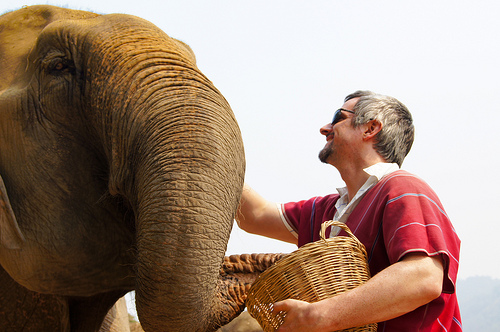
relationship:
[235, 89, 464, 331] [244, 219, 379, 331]
man holding basket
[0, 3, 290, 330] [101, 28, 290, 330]
elephant has trunk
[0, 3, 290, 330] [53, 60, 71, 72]
elephant has right eye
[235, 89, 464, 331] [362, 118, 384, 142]
man has left ear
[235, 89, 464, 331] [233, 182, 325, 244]
man has right arm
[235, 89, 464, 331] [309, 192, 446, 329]
man has left arm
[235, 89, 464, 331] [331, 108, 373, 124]
man wearing sunglasses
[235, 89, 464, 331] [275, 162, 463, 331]
man wearing shirt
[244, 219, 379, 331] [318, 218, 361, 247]
basket has handle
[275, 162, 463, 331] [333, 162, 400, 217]
shirt has collar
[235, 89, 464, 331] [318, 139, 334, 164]
man has goatee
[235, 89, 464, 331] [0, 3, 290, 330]
man with elephant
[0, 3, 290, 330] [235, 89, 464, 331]
elephant standing by man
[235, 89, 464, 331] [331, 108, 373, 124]
man with sunglasses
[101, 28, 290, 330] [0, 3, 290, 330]
trunk on front of elephant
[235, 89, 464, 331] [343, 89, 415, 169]
man has hair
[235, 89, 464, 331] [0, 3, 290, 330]
man touching elephant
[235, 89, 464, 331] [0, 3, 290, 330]
man pats elephant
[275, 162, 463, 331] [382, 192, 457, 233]
shirt has stripe